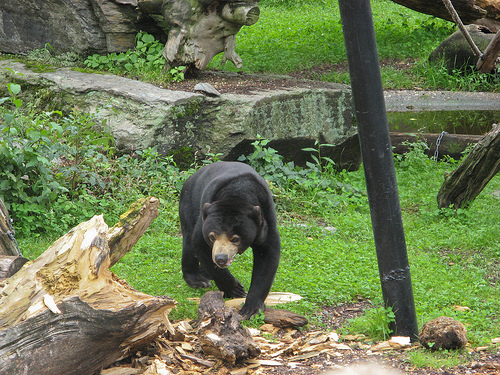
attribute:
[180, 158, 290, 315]
bear cub — black, furry, walking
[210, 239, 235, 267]
snout — white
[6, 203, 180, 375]
log — dead, brown, downed, light brown, scratched, large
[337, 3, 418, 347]
pillar — grey, metal, black, tall, iron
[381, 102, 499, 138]
water — reflected, green, reflective, stagnant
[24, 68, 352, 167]
rock — grey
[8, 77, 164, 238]
vegetation — leafy, green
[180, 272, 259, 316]
paws — black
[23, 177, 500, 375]
grass — green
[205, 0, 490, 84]
grass — green, tall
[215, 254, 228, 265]
nose — dark brown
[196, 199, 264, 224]
ears — small